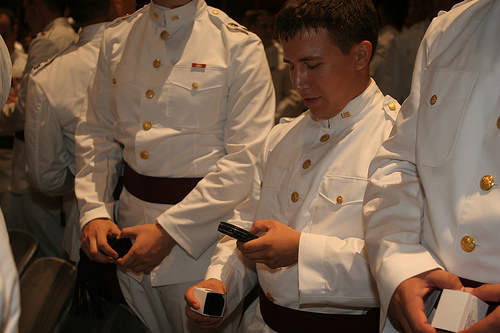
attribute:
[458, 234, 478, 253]
button — gold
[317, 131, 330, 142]
button — gold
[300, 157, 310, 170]
button — gold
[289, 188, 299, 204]
button — gold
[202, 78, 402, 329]
shirt — white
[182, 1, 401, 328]
man — short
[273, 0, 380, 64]
hair — dark, short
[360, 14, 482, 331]
shirt — white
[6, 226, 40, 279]
chair — gray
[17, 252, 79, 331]
chair — gray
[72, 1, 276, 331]
man — tall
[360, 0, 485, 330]
man — tall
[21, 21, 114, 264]
uniform — white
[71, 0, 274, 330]
uniform — white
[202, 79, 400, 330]
uniform — white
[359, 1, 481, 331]
uniform — white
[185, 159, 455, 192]
uniforms —  white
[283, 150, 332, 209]
gold buttons —  gold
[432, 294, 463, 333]
box — white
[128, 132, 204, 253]
belt — wide and black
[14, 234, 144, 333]
chair — gray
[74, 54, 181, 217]
shirt — white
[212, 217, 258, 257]
cell phone — black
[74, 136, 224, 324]
shirt — white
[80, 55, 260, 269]
shirt — long sleeve 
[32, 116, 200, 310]
shirt — white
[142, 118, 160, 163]
buttons — gold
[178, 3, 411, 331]
guy — short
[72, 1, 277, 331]
guy — tall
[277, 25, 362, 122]
face — sweaty